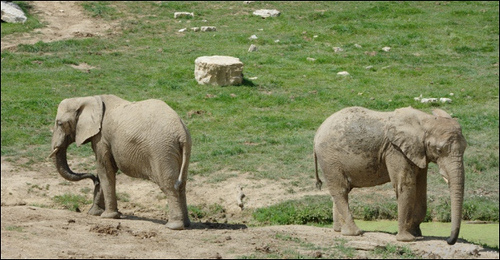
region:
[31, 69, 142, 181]
the head of a elephant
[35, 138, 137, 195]
the trunk of a elephant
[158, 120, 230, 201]
the tail of a elephant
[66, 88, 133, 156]
the ears of a elephant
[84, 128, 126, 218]
the front legs of a elephant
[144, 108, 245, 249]
the back legs of a elephant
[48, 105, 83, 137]
the eye of a elephant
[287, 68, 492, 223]
a big grey elephant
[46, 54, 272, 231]
a elephant in a field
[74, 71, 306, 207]
the body of a elephant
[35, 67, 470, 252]
two elephants walking in green field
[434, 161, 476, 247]
grey elephant trunk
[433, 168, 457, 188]
white elephant tusk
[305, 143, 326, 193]
elephant tail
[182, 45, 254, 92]
large rock in green field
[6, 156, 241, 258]
dirt patch in green field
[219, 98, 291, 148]
patch of green grass in green field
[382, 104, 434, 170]
grey elephant ear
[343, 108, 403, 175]
water stain on elephant side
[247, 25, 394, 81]
rocks in green field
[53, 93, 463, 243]
two elephants facing opposite directions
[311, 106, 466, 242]
the elephant on the right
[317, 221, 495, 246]
green murky water behind the right elephant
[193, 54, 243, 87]
giant boulder with a flat top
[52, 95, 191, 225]
the elephant on the left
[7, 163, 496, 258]
the dirt the elephants are standing on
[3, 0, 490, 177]
green grass field behind the elephants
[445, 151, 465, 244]
the right elephant's trunk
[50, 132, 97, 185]
the left elephant's trunk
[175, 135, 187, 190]
the left elephants tail.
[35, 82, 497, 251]
two elephants are the focus of this picture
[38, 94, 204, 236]
this elephant is in the process of lifting it's trunk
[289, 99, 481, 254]
this elephant appears to have just drank some water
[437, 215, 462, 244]
the end of his trunk is wet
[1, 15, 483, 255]
the area has a lot of green grass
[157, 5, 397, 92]
it is also dotted with rocks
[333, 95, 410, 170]
this elephant appears to have been rolling in the mud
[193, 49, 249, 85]
this rock has a flat top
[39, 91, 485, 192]
both elephants have short tusks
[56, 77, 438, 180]
the elephants have really big ears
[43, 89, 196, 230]
an elephant facing left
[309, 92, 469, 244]
an elephant facing right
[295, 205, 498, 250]
a stream behind the elephant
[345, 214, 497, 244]
the stream is green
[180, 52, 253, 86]
a stump across the stream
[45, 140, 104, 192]
his trunk is twisted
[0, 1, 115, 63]
a dirt path going up the hill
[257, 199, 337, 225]
weeds growing by the stream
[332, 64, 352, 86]
a rock in the lawn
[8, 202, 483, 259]
dirt by the stream